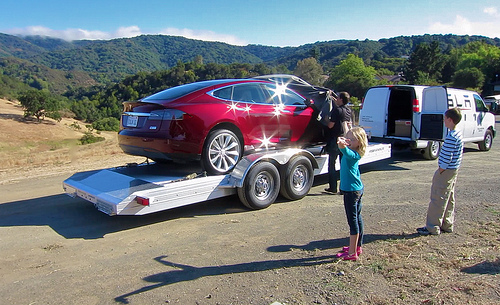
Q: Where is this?
A: This is at the road.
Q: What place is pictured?
A: It is a road.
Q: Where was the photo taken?
A: It was taken at the road.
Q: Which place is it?
A: It is a road.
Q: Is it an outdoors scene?
A: Yes, it is outdoors.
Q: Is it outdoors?
A: Yes, it is outdoors.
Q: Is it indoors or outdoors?
A: It is outdoors.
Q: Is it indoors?
A: No, it is outdoors.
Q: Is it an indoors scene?
A: No, it is outdoors.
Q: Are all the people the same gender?
A: No, they are both male and female.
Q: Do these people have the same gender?
A: No, they are both male and female.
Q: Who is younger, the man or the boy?
A: The boy is younger than the man.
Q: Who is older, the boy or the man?
A: The man is older than the boy.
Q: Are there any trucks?
A: Yes, there is a truck.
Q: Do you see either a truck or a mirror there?
A: Yes, there is a truck.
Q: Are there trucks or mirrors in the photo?
A: Yes, there is a truck.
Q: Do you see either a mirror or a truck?
A: Yes, there is a truck.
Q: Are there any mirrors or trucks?
A: Yes, there is a truck.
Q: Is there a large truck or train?
A: Yes, there is a large truck.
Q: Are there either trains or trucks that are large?
A: Yes, the truck is large.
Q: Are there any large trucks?
A: Yes, there is a large truck.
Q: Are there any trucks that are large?
A: Yes, there is a truck that is large.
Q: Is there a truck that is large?
A: Yes, there is a truck that is large.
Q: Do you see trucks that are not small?
A: Yes, there is a large truck.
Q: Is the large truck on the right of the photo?
A: Yes, the truck is on the right of the image.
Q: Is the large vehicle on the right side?
A: Yes, the truck is on the right of the image.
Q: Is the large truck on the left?
A: No, the truck is on the right of the image.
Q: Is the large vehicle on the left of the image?
A: No, the truck is on the right of the image.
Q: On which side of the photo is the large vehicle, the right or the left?
A: The truck is on the right of the image.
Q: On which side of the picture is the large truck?
A: The truck is on the right of the image.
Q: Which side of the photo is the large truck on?
A: The truck is on the right of the image.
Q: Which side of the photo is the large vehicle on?
A: The truck is on the right of the image.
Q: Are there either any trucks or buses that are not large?
A: No, there is a truck but it is large.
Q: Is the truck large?
A: Yes, the truck is large.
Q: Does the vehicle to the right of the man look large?
A: Yes, the truck is large.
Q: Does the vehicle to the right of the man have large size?
A: Yes, the truck is large.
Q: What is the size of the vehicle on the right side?
A: The truck is large.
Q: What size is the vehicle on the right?
A: The truck is large.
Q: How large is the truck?
A: The truck is large.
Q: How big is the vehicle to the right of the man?
A: The truck is large.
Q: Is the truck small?
A: No, the truck is large.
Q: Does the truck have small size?
A: No, the truck is large.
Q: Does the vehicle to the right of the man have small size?
A: No, the truck is large.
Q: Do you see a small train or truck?
A: No, there is a truck but it is large.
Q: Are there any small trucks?
A: No, there is a truck but it is large.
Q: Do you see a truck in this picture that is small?
A: No, there is a truck but it is large.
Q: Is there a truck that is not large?
A: No, there is a truck but it is large.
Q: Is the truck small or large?
A: The truck is large.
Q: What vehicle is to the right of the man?
A: The vehicle is a truck.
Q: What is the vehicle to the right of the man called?
A: The vehicle is a truck.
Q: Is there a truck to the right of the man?
A: Yes, there is a truck to the right of the man.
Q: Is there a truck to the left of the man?
A: No, the truck is to the right of the man.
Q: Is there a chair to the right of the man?
A: No, there is a truck to the right of the man.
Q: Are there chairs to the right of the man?
A: No, there is a truck to the right of the man.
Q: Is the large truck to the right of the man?
A: Yes, the truck is to the right of the man.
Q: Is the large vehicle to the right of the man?
A: Yes, the truck is to the right of the man.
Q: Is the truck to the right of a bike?
A: No, the truck is to the right of the man.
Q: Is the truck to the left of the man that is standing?
A: No, the truck is to the right of the man.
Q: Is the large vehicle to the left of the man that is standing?
A: No, the truck is to the right of the man.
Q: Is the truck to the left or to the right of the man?
A: The truck is to the right of the man.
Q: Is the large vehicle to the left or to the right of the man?
A: The truck is to the right of the man.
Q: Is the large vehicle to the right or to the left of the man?
A: The truck is to the right of the man.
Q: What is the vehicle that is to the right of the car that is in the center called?
A: The vehicle is a truck.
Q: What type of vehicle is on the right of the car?
A: The vehicle is a truck.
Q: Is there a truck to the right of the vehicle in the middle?
A: Yes, there is a truck to the right of the car.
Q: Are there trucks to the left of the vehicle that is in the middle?
A: No, the truck is to the right of the car.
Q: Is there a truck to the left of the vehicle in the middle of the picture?
A: No, the truck is to the right of the car.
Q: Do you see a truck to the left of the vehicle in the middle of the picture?
A: No, the truck is to the right of the car.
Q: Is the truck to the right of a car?
A: Yes, the truck is to the right of a car.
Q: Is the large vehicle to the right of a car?
A: Yes, the truck is to the right of a car.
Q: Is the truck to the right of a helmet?
A: No, the truck is to the right of a car.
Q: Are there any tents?
A: No, there are no tents.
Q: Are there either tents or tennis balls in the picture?
A: No, there are no tents or tennis balls.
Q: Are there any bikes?
A: No, there are no bikes.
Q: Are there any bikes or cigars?
A: No, there are no bikes or cigars.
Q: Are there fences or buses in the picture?
A: No, there are no fences or buses.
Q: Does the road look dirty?
A: Yes, the road is dirty.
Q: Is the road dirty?
A: Yes, the road is dirty.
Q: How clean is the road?
A: The road is dirty.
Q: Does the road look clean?
A: No, the road is dirty.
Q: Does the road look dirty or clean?
A: The road is dirty.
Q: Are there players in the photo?
A: No, there are no players.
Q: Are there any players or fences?
A: No, there are no players or fences.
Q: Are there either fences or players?
A: No, there are no players or fences.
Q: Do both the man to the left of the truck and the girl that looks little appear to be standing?
A: Yes, both the man and the girl are standing.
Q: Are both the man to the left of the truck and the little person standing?
A: Yes, both the man and the girl are standing.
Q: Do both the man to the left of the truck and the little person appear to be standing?
A: Yes, both the man and the girl are standing.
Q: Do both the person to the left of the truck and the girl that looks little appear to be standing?
A: Yes, both the man and the girl are standing.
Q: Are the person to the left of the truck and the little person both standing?
A: Yes, both the man and the girl are standing.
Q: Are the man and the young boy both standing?
A: Yes, both the man and the boy are standing.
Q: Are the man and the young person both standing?
A: Yes, both the man and the boy are standing.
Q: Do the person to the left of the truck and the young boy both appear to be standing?
A: Yes, both the man and the boy are standing.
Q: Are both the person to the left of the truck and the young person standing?
A: Yes, both the man and the boy are standing.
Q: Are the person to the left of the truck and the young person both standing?
A: Yes, both the man and the boy are standing.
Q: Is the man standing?
A: Yes, the man is standing.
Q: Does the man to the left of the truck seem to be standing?
A: Yes, the man is standing.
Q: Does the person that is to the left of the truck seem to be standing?
A: Yes, the man is standing.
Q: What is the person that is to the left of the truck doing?
A: The man is standing.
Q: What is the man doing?
A: The man is standing.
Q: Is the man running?
A: No, the man is standing.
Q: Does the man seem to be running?
A: No, the man is standing.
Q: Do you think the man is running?
A: No, the man is standing.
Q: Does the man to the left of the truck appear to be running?
A: No, the man is standing.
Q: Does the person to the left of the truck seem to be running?
A: No, the man is standing.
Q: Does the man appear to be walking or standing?
A: The man is standing.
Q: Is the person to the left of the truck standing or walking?
A: The man is standing.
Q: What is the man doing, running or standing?
A: The man is standing.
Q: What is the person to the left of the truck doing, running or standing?
A: The man is standing.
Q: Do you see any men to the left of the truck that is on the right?
A: Yes, there is a man to the left of the truck.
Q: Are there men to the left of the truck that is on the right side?
A: Yes, there is a man to the left of the truck.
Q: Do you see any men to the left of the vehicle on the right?
A: Yes, there is a man to the left of the truck.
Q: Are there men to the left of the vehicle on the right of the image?
A: Yes, there is a man to the left of the truck.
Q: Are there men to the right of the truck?
A: No, the man is to the left of the truck.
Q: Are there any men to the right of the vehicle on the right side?
A: No, the man is to the left of the truck.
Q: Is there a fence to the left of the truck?
A: No, there is a man to the left of the truck.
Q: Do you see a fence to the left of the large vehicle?
A: No, there is a man to the left of the truck.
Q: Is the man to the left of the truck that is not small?
A: Yes, the man is to the left of the truck.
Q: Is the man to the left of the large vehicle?
A: Yes, the man is to the left of the truck.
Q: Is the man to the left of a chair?
A: No, the man is to the left of the truck.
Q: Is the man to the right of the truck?
A: No, the man is to the left of the truck.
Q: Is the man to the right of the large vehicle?
A: No, the man is to the left of the truck.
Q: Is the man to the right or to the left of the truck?
A: The man is to the left of the truck.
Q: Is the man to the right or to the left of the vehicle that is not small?
A: The man is to the left of the truck.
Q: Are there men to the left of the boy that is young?
A: Yes, there is a man to the left of the boy.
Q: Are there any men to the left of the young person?
A: Yes, there is a man to the left of the boy.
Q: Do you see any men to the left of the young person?
A: Yes, there is a man to the left of the boy.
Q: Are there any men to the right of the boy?
A: No, the man is to the left of the boy.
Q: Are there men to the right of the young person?
A: No, the man is to the left of the boy.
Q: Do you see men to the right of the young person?
A: No, the man is to the left of the boy.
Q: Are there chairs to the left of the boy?
A: No, there is a man to the left of the boy.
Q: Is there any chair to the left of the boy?
A: No, there is a man to the left of the boy.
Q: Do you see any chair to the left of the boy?
A: No, there is a man to the left of the boy.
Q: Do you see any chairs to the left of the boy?
A: No, there is a man to the left of the boy.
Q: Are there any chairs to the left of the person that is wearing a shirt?
A: No, there is a man to the left of the boy.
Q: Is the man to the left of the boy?
A: Yes, the man is to the left of the boy.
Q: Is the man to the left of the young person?
A: Yes, the man is to the left of the boy.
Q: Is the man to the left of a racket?
A: No, the man is to the left of the boy.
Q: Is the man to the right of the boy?
A: No, the man is to the left of the boy.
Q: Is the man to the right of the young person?
A: No, the man is to the left of the boy.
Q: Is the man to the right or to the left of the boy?
A: The man is to the left of the boy.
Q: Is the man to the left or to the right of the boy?
A: The man is to the left of the boy.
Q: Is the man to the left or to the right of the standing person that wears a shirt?
A: The man is to the left of the boy.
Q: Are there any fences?
A: No, there are no fences.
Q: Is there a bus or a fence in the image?
A: No, there are no fences or buses.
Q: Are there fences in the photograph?
A: No, there are no fences.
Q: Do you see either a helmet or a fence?
A: No, there are no fences or helmets.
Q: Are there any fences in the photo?
A: No, there are no fences.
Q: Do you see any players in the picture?
A: No, there are no players.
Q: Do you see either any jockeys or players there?
A: No, there are no players or jockeys.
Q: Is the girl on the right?
A: Yes, the girl is on the right of the image.